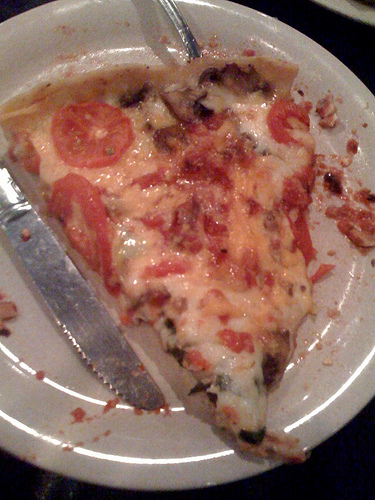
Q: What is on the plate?
A: Food.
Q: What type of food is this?
A: Pizza.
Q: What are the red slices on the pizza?
A: Tomatoes.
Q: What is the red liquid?
A: Sauce.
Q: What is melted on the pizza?
A: Cheese.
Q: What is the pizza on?
A: Plate.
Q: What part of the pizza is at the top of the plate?
A: Crust.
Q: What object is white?
A: Plate.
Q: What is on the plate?
A: The pizza.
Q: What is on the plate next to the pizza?
A: The knife.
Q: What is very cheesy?
A: The pizza.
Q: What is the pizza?
A: Thin crust.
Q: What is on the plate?
A: The pizza.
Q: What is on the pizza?
A: The topping.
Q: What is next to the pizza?
A: The knife.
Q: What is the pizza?
A: One piece.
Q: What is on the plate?
A: The pizza.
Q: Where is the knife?
A: On a plate.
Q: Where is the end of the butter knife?
A: On the plate.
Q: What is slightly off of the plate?
A: The tip of pizza.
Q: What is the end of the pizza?
A: The crust.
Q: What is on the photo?
A: A pizza on a plate.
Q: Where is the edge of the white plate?
A: Bottom of photo.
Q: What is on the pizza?
A: Pizza cheese and sauce.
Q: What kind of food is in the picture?
A: Pizza.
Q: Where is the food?
A: On the plate.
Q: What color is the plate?
A: White.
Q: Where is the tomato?
A: On the pizza.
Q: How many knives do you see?
A: One.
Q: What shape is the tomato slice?
A: Round.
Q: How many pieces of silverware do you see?
A: Two.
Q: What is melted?
A: Cheese.